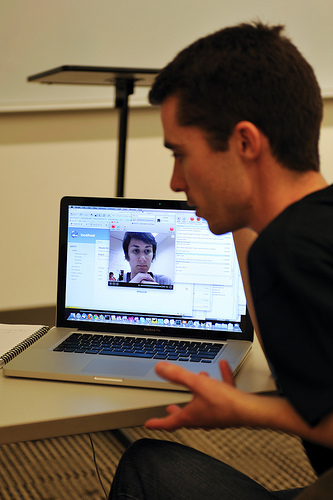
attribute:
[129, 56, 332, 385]
man — sitting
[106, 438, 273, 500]
jeans — blue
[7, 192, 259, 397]
laptop — open, silver, mac, grey, on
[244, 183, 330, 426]
shirt — black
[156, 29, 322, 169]
hair — brown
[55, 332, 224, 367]
keys — black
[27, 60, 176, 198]
lamp — black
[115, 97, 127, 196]
pole — black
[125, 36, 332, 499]
person — thinking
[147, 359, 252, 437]
hand — moving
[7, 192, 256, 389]
macbook — silver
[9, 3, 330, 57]
ceiling — white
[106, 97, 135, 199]
post — black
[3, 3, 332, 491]
room — white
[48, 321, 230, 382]
keyboard — black, grey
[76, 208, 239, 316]
screen — black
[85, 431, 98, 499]
cord — black